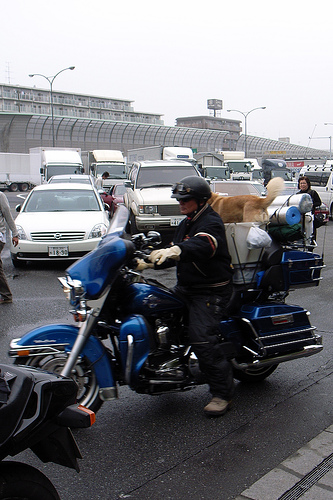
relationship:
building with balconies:
[13, 84, 153, 121] [76, 107, 164, 125]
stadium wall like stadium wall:
[0, 102, 333, 159] [184, 127, 232, 153]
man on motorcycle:
[160, 180, 231, 422] [47, 249, 316, 381]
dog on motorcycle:
[204, 186, 295, 225] [47, 249, 316, 381]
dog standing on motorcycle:
[204, 186, 295, 225] [47, 249, 316, 381]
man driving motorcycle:
[160, 180, 231, 422] [47, 249, 316, 381]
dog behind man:
[204, 186, 295, 225] [160, 180, 231, 422]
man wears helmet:
[160, 180, 231, 422] [172, 177, 211, 211]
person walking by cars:
[99, 174, 111, 210] [34, 175, 233, 234]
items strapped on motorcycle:
[245, 225, 327, 302] [47, 249, 316, 381]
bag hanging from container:
[240, 225, 296, 252] [228, 230, 248, 252]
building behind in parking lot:
[13, 84, 153, 121] [0, 142, 333, 499]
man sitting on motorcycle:
[160, 180, 231, 422] [47, 249, 316, 381]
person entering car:
[99, 174, 111, 210] [8, 190, 107, 263]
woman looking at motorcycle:
[293, 177, 326, 224] [47, 249, 316, 381]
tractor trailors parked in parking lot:
[32, 154, 278, 184] [297, 390, 304, 416]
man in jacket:
[160, 180, 231, 422] [168, 217, 227, 288]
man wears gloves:
[160, 180, 231, 422] [150, 243, 180, 264]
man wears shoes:
[160, 180, 231, 422] [202, 393, 248, 429]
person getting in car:
[99, 174, 111, 210] [8, 190, 107, 263]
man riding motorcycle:
[160, 180, 231, 422] [47, 249, 316, 381]